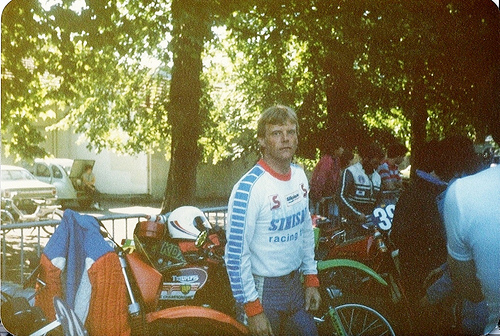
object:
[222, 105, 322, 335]
man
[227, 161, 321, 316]
shirt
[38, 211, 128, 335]
jacket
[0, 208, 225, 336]
motorcycle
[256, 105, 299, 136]
hair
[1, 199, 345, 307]
barrier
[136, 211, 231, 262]
motorcycle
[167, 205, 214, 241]
helmet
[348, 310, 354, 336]
spoke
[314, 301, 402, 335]
tire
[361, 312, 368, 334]
spoke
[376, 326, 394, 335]
spoke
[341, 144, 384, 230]
man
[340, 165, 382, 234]
jacket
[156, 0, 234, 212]
tree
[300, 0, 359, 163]
tree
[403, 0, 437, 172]
tree